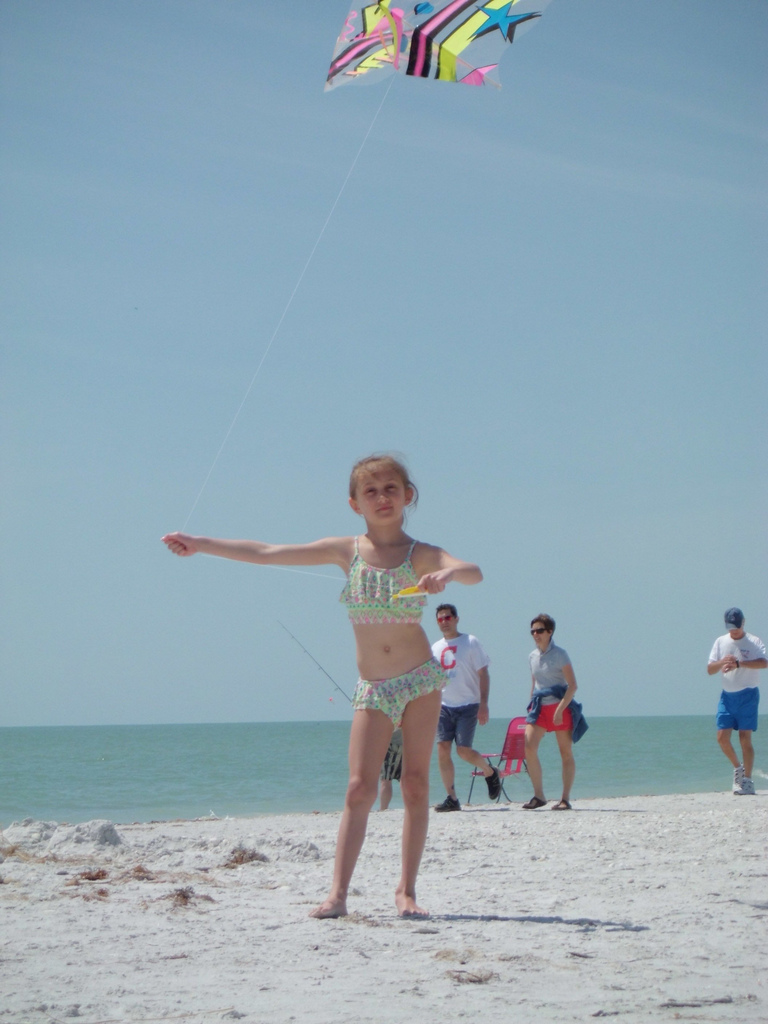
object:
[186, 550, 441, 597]
kitestring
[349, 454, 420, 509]
girl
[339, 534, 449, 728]
bikini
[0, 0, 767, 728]
sky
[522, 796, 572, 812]
sandals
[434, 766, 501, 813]
shoes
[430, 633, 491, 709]
shirt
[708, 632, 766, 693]
shirt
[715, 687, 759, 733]
shorts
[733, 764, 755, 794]
shoes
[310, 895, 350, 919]
foot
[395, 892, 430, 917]
foot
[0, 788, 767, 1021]
beach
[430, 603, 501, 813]
man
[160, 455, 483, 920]
girl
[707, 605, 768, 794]
man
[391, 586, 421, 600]
holder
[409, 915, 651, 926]
shadow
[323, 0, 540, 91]
kite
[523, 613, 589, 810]
woman